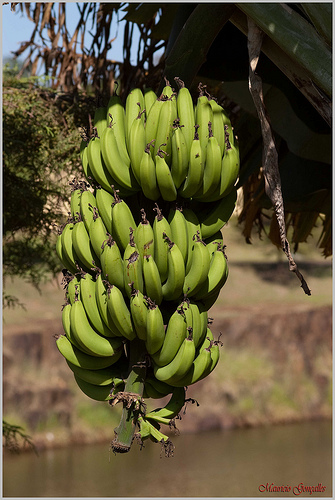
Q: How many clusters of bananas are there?
A: One.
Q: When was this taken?
A: During the day.